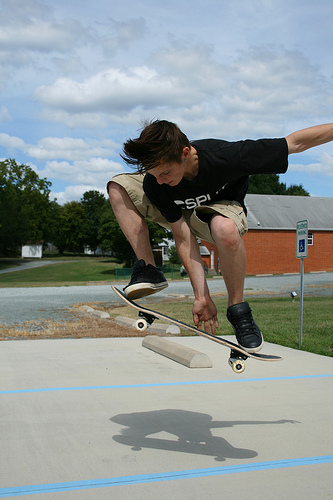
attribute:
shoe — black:
[123, 261, 170, 299]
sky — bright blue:
[0, 0, 330, 177]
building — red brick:
[193, 191, 331, 276]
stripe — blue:
[1, 372, 332, 395]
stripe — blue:
[1, 450, 331, 498]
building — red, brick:
[221, 178, 332, 291]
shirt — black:
[132, 138, 290, 218]